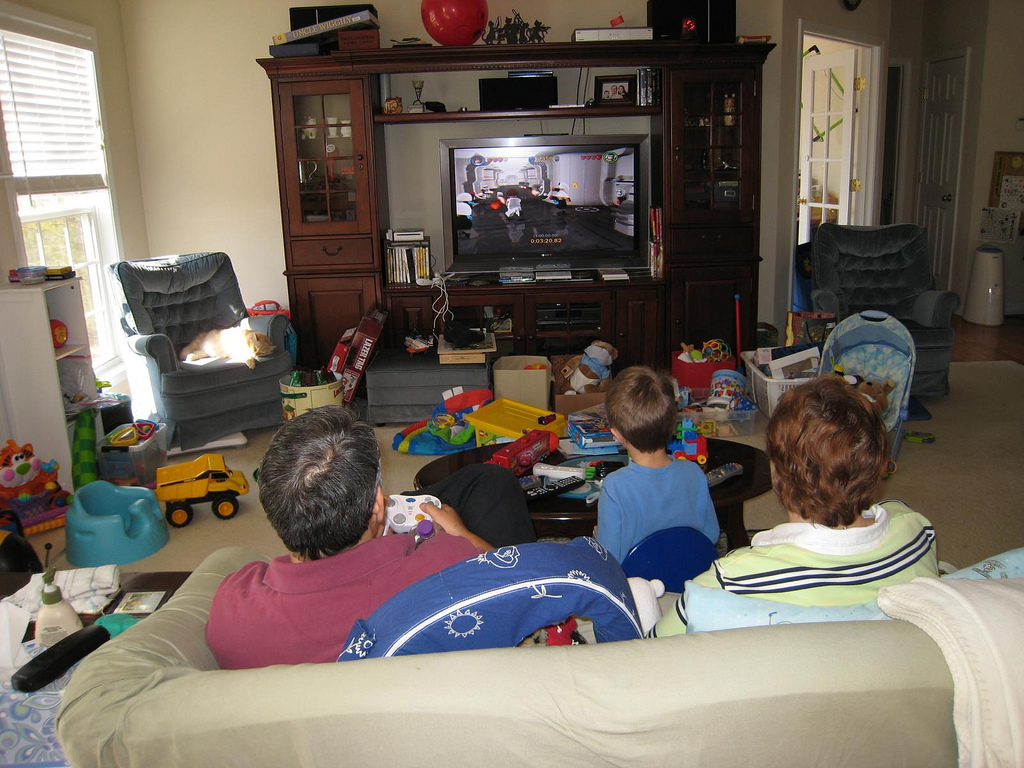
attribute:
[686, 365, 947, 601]
person — playing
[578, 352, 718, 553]
person — playing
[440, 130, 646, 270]
television — large,  flat, flat screen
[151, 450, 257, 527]
dump truck — yellow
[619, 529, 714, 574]
chair — blue, plastic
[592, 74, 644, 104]
picture — framed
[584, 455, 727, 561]
shirt — blue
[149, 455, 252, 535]
truck — yellow, black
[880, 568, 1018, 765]
blanket — white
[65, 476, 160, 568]
chair — blue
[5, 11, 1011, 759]
room — messy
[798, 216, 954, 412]
chair — blue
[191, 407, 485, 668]
person — playing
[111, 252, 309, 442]
chair — gray